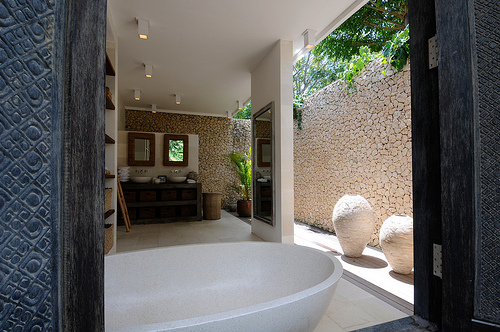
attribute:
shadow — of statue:
[338, 246, 389, 272]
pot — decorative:
[320, 186, 376, 263]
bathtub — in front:
[104, 240, 342, 330]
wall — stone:
[295, 34, 410, 251]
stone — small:
[377, 116, 391, 134]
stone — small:
[373, 153, 387, 172]